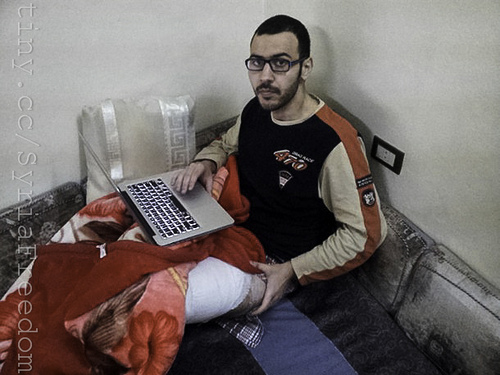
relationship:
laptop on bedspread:
[78, 131, 236, 248] [0, 153, 266, 373]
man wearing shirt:
[172, 13, 390, 327] [192, 93, 389, 286]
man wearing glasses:
[172, 13, 390, 327] [245, 54, 310, 74]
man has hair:
[172, 13, 390, 327] [248, 14, 311, 64]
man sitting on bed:
[172, 13, 390, 327] [2, 115, 497, 373]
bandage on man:
[183, 255, 253, 326] [172, 13, 390, 327]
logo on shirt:
[273, 147, 308, 173] [192, 93, 389, 286]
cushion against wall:
[86, 92, 196, 204] [1, 1, 264, 210]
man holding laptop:
[172, 13, 390, 327] [78, 131, 236, 248]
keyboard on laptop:
[125, 177, 197, 239] [78, 131, 236, 248]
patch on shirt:
[362, 188, 379, 210] [192, 93, 389, 286]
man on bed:
[172, 13, 390, 327] [2, 115, 497, 373]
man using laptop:
[172, 13, 390, 327] [78, 131, 236, 248]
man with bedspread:
[172, 13, 390, 327] [0, 153, 266, 373]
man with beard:
[172, 13, 390, 327] [251, 74, 305, 111]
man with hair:
[172, 13, 390, 327] [248, 14, 311, 64]